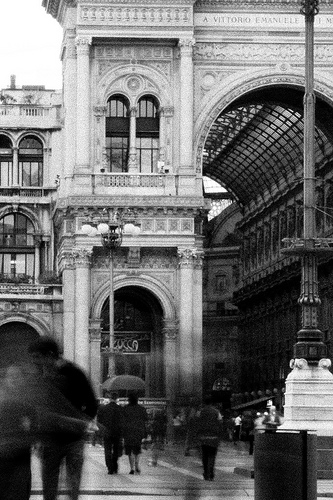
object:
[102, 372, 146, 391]
umbrella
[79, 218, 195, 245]
umbrella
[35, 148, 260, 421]
rain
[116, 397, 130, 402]
rod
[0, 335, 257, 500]
people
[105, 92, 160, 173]
two windows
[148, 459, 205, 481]
line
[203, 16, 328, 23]
writing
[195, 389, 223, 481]
person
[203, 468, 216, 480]
walking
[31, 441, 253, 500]
ground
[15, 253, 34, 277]
window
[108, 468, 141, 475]
feet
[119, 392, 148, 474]
woman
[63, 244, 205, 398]
columns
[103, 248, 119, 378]
lamppost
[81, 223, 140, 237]
circle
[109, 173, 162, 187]
railing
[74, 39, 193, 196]
columns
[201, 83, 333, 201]
beams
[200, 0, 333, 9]
roof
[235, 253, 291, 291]
border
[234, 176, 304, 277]
medallions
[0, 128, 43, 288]
arches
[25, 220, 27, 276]
vertical line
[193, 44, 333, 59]
borders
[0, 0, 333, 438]
building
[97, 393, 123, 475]
man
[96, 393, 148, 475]
people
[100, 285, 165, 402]
arch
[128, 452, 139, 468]
skin